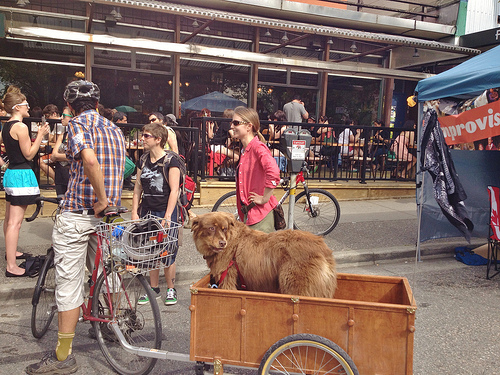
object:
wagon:
[190, 269, 417, 375]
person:
[0, 84, 49, 279]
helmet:
[62, 79, 100, 104]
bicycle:
[23, 194, 183, 374]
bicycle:
[210, 158, 340, 238]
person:
[132, 123, 184, 305]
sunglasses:
[141, 133, 157, 138]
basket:
[93, 215, 184, 276]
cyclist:
[24, 79, 124, 374]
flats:
[5, 252, 33, 261]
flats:
[5, 266, 32, 277]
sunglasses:
[11, 102, 30, 110]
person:
[229, 105, 286, 234]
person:
[145, 112, 184, 205]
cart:
[188, 258, 417, 375]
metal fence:
[0, 115, 417, 192]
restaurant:
[2, 0, 497, 189]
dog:
[189, 211, 336, 298]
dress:
[0, 119, 42, 206]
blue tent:
[405, 46, 499, 243]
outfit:
[1, 120, 41, 205]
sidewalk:
[0, 192, 482, 287]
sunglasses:
[230, 120, 249, 126]